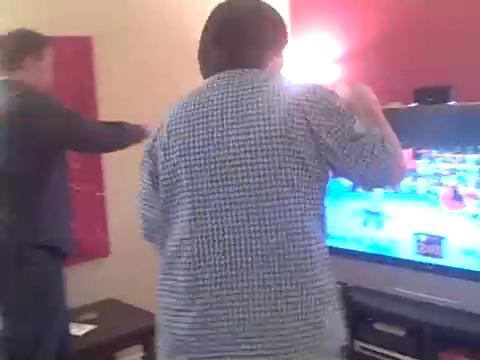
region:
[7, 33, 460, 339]
Two people are standing.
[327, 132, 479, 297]
TV screen is on.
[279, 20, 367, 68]
Light is on.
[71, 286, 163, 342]
Table is brown color.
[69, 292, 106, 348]
Paper is in table.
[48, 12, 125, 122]
Picture is hanging in the wall.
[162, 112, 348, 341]
Man is wearing black and white shirt.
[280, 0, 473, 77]
Wall is pink color.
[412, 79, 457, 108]
Box is black color.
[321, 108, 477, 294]
TV is grey color.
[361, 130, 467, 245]
television next to people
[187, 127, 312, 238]
shirt on the back of the person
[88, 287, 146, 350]
table on the ground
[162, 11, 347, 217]
man with back towards camera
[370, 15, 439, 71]
red wall in the room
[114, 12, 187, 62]
white wall in room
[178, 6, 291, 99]
hair on man's head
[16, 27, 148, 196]
man with arm out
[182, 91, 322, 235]
checkered shirt on man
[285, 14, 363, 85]
light in the room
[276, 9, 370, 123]
bright light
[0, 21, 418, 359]
Two men are standing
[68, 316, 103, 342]
White paper on brown table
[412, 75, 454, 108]
Black box on tv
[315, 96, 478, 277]
A large tv screen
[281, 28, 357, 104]
A blurred light in corner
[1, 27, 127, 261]
A red piece of artwork on wall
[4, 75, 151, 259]
Man wears a black shirt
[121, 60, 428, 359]
Man wears a black and white shirt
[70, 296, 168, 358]
A dark brown table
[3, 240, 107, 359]
Man wears black pants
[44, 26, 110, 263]
Red artwork on wall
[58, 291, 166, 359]
Low dark brown table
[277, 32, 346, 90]
Very bright lamp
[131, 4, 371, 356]
Person wearing a blue and white shirt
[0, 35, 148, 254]
Person in blue long sleeved shirt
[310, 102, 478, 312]
Big screen television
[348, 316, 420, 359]
Cable receiver box under TV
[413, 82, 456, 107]
Black box on top of TV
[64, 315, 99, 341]
White paper on coffee table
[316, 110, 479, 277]
Video game on TV